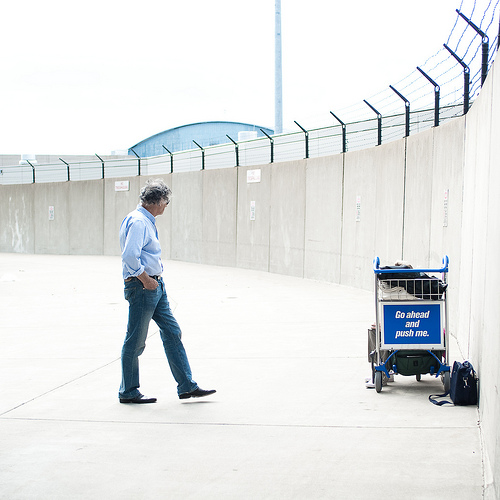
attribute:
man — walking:
[126, 188, 206, 409]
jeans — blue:
[123, 283, 194, 395]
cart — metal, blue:
[368, 260, 458, 395]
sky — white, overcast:
[13, 15, 357, 118]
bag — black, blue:
[448, 359, 479, 404]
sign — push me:
[379, 305, 447, 347]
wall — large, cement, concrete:
[1, 181, 480, 296]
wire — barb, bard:
[2, 131, 309, 184]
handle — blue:
[372, 261, 454, 280]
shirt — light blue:
[123, 215, 161, 277]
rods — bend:
[87, 149, 180, 178]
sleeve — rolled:
[125, 261, 150, 282]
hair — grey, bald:
[141, 181, 170, 211]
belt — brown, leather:
[126, 273, 171, 285]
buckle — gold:
[155, 273, 165, 287]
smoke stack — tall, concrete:
[266, 5, 290, 133]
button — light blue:
[154, 234, 164, 278]